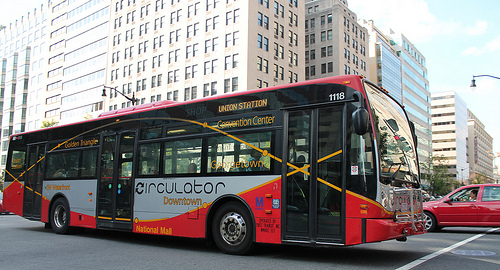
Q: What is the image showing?
A: It is showing a city.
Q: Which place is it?
A: It is a city.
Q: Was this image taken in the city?
A: Yes, it was taken in the city.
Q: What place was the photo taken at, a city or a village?
A: It was taken at a city.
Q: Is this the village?
A: No, it is the city.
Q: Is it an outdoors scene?
A: Yes, it is outdoors.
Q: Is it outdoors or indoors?
A: It is outdoors.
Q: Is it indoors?
A: No, it is outdoors.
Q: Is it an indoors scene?
A: No, it is outdoors.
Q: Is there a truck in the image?
A: No, there are no trucks.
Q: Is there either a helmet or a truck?
A: No, there are no trucks or helmets.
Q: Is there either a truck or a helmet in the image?
A: No, there are no trucks or helmets.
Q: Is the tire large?
A: Yes, the tire is large.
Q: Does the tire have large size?
A: Yes, the tire is large.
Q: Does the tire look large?
A: Yes, the tire is large.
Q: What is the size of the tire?
A: The tire is large.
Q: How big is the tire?
A: The tire is large.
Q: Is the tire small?
A: No, the tire is large.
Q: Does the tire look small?
A: No, the tire is large.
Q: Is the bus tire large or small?
A: The tire is large.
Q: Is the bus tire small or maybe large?
A: The tire is large.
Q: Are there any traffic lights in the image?
A: No, there are no traffic lights.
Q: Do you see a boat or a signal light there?
A: No, there are no traffic lights or boats.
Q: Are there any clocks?
A: No, there are no clocks.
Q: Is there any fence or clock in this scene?
A: No, there are no clocks or fences.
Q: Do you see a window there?
A: Yes, there are windows.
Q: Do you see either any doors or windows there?
A: Yes, there are windows.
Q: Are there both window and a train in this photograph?
A: No, there are windows but no trains.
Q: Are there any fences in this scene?
A: No, there are no fences.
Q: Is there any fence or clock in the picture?
A: No, there are no fences or clocks.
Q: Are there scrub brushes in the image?
A: No, there are no scrub brushes.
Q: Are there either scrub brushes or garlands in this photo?
A: No, there are no scrub brushes or garlands.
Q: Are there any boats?
A: No, there are no boats.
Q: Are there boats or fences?
A: No, there are no boats or fences.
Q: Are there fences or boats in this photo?
A: No, there are no boats or fences.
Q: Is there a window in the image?
A: Yes, there are windows.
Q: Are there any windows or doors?
A: Yes, there are windows.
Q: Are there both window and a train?
A: No, there are windows but no trains.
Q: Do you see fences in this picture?
A: No, there are no fences.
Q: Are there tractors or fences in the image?
A: No, there are no fences or tractors.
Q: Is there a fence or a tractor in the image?
A: No, there are no fences or tractors.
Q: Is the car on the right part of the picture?
A: Yes, the car is on the right of the image.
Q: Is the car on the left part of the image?
A: No, the car is on the right of the image.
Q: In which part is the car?
A: The car is on the right of the image.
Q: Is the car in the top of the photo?
A: No, the car is in the bottom of the image.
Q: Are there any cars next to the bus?
A: Yes, there is a car next to the bus.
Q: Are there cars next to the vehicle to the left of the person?
A: Yes, there is a car next to the bus.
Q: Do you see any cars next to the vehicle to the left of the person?
A: Yes, there is a car next to the bus.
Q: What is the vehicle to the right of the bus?
A: The vehicle is a car.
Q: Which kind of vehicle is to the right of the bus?
A: The vehicle is a car.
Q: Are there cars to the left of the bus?
A: No, the car is to the right of the bus.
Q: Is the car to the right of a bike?
A: No, the car is to the right of a bus.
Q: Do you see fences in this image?
A: No, there are no fences.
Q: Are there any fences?
A: No, there are no fences.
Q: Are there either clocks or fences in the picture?
A: No, there are no fences or clocks.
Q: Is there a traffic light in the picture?
A: No, there are no traffic lights.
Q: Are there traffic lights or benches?
A: No, there are no traffic lights or benches.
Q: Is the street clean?
A: Yes, the street is clean.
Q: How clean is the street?
A: The street is clean.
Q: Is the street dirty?
A: No, the street is clean.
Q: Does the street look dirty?
A: No, the street is clean.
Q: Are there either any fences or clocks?
A: No, there are no fences or clocks.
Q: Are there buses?
A: Yes, there is a bus.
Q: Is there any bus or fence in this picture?
A: Yes, there is a bus.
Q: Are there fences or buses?
A: Yes, there is a bus.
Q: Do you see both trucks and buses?
A: No, there is a bus but no trucks.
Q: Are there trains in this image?
A: No, there are no trains.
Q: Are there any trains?
A: No, there are no trains.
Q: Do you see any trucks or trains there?
A: No, there are no trains or trucks.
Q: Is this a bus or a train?
A: This is a bus.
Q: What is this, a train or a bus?
A: This is a bus.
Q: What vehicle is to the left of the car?
A: The vehicle is a bus.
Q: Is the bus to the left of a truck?
A: No, the bus is to the left of the car.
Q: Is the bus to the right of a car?
A: No, the bus is to the left of a car.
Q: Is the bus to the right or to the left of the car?
A: The bus is to the left of the car.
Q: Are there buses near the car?
A: Yes, there is a bus near the car.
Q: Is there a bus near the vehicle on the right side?
A: Yes, there is a bus near the car.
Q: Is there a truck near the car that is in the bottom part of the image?
A: No, there is a bus near the car.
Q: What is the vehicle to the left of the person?
A: The vehicle is a bus.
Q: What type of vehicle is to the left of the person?
A: The vehicle is a bus.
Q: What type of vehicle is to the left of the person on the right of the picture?
A: The vehicle is a bus.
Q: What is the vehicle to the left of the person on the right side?
A: The vehicle is a bus.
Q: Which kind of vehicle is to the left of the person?
A: The vehicle is a bus.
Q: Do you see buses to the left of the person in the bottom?
A: Yes, there is a bus to the left of the person.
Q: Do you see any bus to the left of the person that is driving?
A: Yes, there is a bus to the left of the person.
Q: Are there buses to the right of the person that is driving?
A: No, the bus is to the left of the person.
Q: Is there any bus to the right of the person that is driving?
A: No, the bus is to the left of the person.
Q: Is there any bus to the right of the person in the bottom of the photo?
A: No, the bus is to the left of the person.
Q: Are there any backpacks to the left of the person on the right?
A: No, there is a bus to the left of the person.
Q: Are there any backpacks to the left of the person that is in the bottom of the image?
A: No, there is a bus to the left of the person.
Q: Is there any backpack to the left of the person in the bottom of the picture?
A: No, there is a bus to the left of the person.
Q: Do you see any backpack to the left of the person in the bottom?
A: No, there is a bus to the left of the person.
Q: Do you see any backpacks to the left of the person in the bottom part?
A: No, there is a bus to the left of the person.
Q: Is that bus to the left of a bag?
A: No, the bus is to the left of a person.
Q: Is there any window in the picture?
A: Yes, there are windows.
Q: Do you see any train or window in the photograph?
A: Yes, there are windows.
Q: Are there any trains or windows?
A: Yes, there are windows.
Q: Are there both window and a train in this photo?
A: No, there are windows but no trains.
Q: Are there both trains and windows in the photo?
A: No, there are windows but no trains.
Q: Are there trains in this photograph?
A: No, there are no trains.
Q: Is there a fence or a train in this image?
A: No, there are no trains or fences.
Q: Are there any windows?
A: Yes, there are windows.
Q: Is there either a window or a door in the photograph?
A: Yes, there are windows.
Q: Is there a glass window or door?
A: Yes, there are glass windows.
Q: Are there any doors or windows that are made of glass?
A: Yes, the windows are made of glass.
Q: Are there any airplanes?
A: No, there are no airplanes.